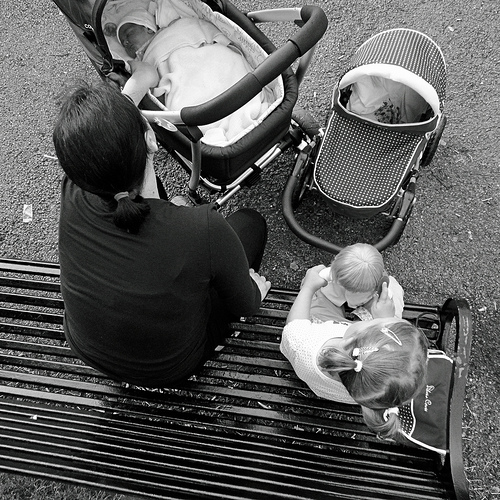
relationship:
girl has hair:
[52, 60, 271, 387] [54, 78, 149, 231]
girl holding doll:
[258, 271, 456, 446] [305, 231, 405, 323]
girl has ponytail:
[30, 77, 255, 389] [319, 346, 371, 375]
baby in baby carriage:
[116, 8, 159, 60] [53, 0, 328, 210]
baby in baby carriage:
[109, 5, 186, 73] [63, 6, 331, 197]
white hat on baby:
[109, 9, 156, 38] [115, 7, 156, 59]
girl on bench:
[52, 60, 271, 387] [2, 249, 475, 499]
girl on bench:
[279, 264, 428, 444] [2, 249, 475, 499]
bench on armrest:
[2, 249, 475, 499] [437, 290, 482, 498]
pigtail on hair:
[314, 347, 362, 376] [321, 323, 433, 412]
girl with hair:
[52, 60, 271, 387] [54, 78, 149, 231]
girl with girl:
[52, 60, 271, 387] [279, 264, 428, 444]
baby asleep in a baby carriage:
[116, 8, 159, 60] [53, 0, 328, 210]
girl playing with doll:
[279, 264, 428, 444] [318, 248, 398, 318]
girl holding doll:
[279, 264, 428, 444] [315, 242, 397, 321]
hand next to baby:
[126, 48, 171, 102] [111, 10, 265, 137]